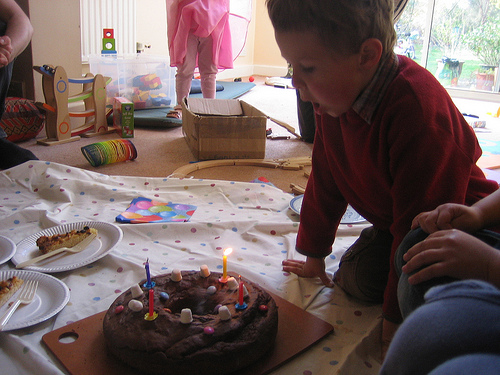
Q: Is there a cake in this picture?
A: Yes, there is a cake.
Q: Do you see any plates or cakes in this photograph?
A: Yes, there is a cake.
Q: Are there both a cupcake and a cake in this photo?
A: No, there is a cake but no cupcakes.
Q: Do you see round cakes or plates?
A: Yes, there is a round cake.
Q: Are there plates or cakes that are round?
A: Yes, the cake is round.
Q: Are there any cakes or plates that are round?
A: Yes, the cake is round.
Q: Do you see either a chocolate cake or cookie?
A: Yes, there is a chocolate cake.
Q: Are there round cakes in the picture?
A: Yes, there is a round cake.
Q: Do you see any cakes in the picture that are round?
A: Yes, there is a cake that is round.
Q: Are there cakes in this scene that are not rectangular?
A: Yes, there is a round cake.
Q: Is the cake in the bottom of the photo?
A: Yes, the cake is in the bottom of the image.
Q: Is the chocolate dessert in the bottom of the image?
A: Yes, the cake is in the bottom of the image.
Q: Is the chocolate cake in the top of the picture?
A: No, the cake is in the bottom of the image.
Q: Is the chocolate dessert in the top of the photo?
A: No, the cake is in the bottom of the image.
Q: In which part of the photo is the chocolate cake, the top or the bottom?
A: The cake is in the bottom of the image.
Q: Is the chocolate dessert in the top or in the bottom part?
A: The cake is in the bottom of the image.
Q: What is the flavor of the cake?
A: This is a chocolate cake.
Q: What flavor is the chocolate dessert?
A: This is a chocolate cake.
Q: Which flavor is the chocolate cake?
A: This is a chocolate cake.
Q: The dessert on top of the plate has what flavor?
A: This is a chocolate cake.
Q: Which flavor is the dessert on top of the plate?
A: This is a chocolate cake.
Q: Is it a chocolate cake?
A: Yes, this is a chocolate cake.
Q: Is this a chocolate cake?
A: Yes, this is a chocolate cake.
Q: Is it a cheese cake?
A: No, this is a chocolate cake.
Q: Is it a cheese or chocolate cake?
A: This is a chocolate cake.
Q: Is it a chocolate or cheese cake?
A: This is a chocolate cake.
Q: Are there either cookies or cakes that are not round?
A: No, there is a cake but it is round.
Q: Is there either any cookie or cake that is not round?
A: No, there is a cake but it is round.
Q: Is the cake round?
A: Yes, the cake is round.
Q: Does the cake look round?
A: Yes, the cake is round.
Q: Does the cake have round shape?
A: Yes, the cake is round.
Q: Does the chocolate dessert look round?
A: Yes, the cake is round.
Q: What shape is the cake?
A: The cake is round.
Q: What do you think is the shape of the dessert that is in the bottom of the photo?
A: The cake is round.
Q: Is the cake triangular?
A: No, the cake is round.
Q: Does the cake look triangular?
A: No, the cake is round.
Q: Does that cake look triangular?
A: No, the cake is round.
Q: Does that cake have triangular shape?
A: No, the cake is round.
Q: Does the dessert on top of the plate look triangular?
A: No, the cake is round.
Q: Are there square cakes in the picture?
A: No, there is a cake but it is round.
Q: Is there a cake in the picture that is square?
A: No, there is a cake but it is round.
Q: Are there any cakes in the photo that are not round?
A: No, there is a cake but it is round.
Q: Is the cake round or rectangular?
A: The cake is round.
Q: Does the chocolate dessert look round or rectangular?
A: The cake is round.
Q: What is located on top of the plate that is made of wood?
A: The cake is on top of the plate.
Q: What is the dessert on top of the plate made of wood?
A: The dessert is a cake.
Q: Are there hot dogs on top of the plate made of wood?
A: No, there is a cake on top of the plate.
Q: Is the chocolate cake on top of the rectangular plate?
A: Yes, the cake is on top of the plate.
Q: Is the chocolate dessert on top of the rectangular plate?
A: Yes, the cake is on top of the plate.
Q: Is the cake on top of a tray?
A: No, the cake is on top of the plate.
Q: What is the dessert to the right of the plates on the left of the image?
A: The dessert is a cake.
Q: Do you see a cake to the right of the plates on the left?
A: Yes, there is a cake to the right of the plates.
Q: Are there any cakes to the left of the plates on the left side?
A: No, the cake is to the right of the plates.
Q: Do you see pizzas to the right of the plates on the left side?
A: No, there is a cake to the right of the plates.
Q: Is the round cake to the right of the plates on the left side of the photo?
A: Yes, the cake is to the right of the plates.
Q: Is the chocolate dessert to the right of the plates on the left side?
A: Yes, the cake is to the right of the plates.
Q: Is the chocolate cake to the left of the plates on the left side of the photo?
A: No, the cake is to the right of the plates.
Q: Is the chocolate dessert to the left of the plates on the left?
A: No, the cake is to the right of the plates.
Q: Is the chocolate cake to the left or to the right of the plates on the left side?
A: The cake is to the right of the plates.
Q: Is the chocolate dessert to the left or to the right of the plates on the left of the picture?
A: The cake is to the right of the plates.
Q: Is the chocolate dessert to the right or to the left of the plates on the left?
A: The cake is to the right of the plates.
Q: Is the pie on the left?
A: Yes, the pie is on the left of the image.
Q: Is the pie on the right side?
A: No, the pie is on the left of the image.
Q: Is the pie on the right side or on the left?
A: The pie is on the left of the image.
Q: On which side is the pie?
A: The pie is on the left of the image.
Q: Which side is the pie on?
A: The pie is on the left of the image.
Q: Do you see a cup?
A: No, there are no cups.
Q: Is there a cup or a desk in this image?
A: No, there are no cups or desks.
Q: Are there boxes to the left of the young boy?
A: Yes, there is a box to the left of the boy.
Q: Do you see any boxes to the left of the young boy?
A: Yes, there is a box to the left of the boy.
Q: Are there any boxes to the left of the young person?
A: Yes, there is a box to the left of the boy.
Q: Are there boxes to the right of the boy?
A: No, the box is to the left of the boy.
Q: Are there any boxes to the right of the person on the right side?
A: No, the box is to the left of the boy.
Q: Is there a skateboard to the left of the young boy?
A: No, there is a box to the left of the boy.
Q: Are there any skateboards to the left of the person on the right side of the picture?
A: No, there is a box to the left of the boy.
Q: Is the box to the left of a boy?
A: Yes, the box is to the left of a boy.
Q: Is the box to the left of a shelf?
A: No, the box is to the left of a boy.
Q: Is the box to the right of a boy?
A: No, the box is to the left of a boy.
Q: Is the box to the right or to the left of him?
A: The box is to the left of the boy.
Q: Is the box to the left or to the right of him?
A: The box is to the left of the boy.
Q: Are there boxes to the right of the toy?
A: Yes, there is a box to the right of the toy.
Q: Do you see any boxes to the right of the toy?
A: Yes, there is a box to the right of the toy.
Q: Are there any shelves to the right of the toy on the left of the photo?
A: No, there is a box to the right of the toy.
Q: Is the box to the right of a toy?
A: Yes, the box is to the right of a toy.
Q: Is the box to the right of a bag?
A: No, the box is to the right of a toy.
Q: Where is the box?
A: The box is on the floor.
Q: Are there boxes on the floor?
A: Yes, there is a box on the floor.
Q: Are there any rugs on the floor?
A: No, there is a box on the floor.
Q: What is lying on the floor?
A: The box is lying on the floor.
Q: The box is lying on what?
A: The box is lying on the floor.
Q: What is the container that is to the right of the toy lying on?
A: The box is lying on the floor.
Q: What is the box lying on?
A: The box is lying on the floor.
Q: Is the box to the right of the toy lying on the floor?
A: Yes, the box is lying on the floor.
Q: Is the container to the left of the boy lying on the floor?
A: Yes, the box is lying on the floor.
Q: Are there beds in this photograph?
A: No, there are no beds.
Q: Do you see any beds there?
A: No, there are no beds.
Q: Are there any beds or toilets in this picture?
A: No, there are no beds or toilets.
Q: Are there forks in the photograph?
A: Yes, there is a fork.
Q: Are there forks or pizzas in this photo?
A: Yes, there is a fork.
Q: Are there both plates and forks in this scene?
A: Yes, there are both a fork and a plate.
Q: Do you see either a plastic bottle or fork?
A: Yes, there is a plastic fork.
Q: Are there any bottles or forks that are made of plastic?
A: Yes, the fork is made of plastic.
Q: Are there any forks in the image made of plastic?
A: Yes, there is a fork that is made of plastic.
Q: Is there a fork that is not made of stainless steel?
A: Yes, there is a fork that is made of plastic.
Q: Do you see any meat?
A: No, there is no meat.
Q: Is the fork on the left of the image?
A: Yes, the fork is on the left of the image.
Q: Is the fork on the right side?
A: No, the fork is on the left of the image.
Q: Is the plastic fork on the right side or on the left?
A: The fork is on the left of the image.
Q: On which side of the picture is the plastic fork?
A: The fork is on the left of the image.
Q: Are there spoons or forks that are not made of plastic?
A: No, there is a fork but it is made of plastic.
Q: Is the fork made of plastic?
A: Yes, the fork is made of plastic.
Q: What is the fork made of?
A: The fork is made of plastic.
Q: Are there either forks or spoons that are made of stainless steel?
A: No, there is a fork but it is made of plastic.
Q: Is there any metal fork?
A: No, there is a fork but it is made of plastic.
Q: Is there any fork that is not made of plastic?
A: No, there is a fork but it is made of plastic.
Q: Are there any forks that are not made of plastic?
A: No, there is a fork but it is made of plastic.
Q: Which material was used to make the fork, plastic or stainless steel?
A: The fork is made of plastic.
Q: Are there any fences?
A: No, there are no fences.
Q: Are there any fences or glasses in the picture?
A: No, there are no fences or glasses.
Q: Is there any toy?
A: Yes, there is a toy.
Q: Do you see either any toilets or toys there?
A: Yes, there is a toy.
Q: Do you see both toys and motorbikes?
A: No, there is a toy but no motorcycles.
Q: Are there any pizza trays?
A: No, there are no pizza trays.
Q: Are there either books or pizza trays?
A: No, there are no pizza trays or books.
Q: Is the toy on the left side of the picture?
A: Yes, the toy is on the left of the image.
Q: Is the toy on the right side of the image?
A: No, the toy is on the left of the image.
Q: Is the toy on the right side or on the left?
A: The toy is on the left of the image.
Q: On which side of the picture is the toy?
A: The toy is on the left of the image.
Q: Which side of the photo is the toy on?
A: The toy is on the left of the image.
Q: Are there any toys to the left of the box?
A: Yes, there is a toy to the left of the box.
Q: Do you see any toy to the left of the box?
A: Yes, there is a toy to the left of the box.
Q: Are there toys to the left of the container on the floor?
A: Yes, there is a toy to the left of the box.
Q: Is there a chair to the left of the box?
A: No, there is a toy to the left of the box.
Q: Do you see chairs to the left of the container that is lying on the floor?
A: No, there is a toy to the left of the box.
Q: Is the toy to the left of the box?
A: Yes, the toy is to the left of the box.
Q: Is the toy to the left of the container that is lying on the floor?
A: Yes, the toy is to the left of the box.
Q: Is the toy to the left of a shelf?
A: No, the toy is to the left of the box.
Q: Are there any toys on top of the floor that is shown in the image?
A: Yes, there is a toy on top of the floor.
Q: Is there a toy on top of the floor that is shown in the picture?
A: Yes, there is a toy on top of the floor.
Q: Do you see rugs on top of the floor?
A: No, there is a toy on top of the floor.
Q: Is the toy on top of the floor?
A: Yes, the toy is on top of the floor.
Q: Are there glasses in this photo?
A: No, there are no glasses.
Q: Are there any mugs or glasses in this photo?
A: No, there are no glasses or mugs.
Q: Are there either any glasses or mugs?
A: No, there are no glasses or mugs.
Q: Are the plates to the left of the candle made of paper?
A: Yes, the plates are made of paper.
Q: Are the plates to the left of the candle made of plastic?
A: No, the plates are made of paper.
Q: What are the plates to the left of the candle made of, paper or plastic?
A: The plates are made of paper.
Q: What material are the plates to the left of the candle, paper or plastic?
A: The plates are made of paper.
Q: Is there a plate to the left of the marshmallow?
A: Yes, there are plates to the left of the marshmallow.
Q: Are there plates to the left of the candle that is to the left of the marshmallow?
A: Yes, there are plates to the left of the candle.